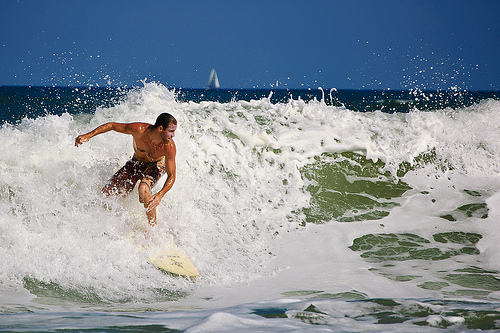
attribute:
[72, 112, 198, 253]
man — topless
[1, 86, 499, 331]
water — green, white, blue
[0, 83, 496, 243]
wave — white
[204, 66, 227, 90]
sailboat — white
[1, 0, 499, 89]
sky — blue, clear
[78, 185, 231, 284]
surfboard — yellow, pointed